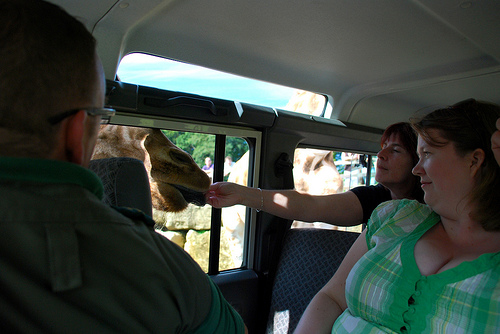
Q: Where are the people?
A: Inside a bus.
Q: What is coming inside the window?
A: A giraffe.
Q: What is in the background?
A: Another animal.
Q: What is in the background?
A: Other people and green trees.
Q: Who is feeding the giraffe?
A: A woman.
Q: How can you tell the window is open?
A: The giraffe is eating past it.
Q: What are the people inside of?
A: A bus.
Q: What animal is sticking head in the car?
A: Giraffe.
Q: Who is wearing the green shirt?
A: Woman closest to the camera.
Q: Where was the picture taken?
A: Inside car.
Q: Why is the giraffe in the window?
A: Get food.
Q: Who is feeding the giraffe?
A: Woman in back.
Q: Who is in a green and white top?
A: Woman on right.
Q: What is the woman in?
A: Car.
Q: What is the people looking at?
A: Animals.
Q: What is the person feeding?
A: Giraffe.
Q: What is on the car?
A: Some people.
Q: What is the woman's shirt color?
A: Green and white.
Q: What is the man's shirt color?
A: Green.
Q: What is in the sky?
A: Clouds.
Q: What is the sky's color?
A: Blue.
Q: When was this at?
A: During the day time.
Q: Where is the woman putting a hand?
A: Through the window to the car.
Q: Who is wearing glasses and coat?
A: A man.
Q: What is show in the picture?
A: The side window of the car.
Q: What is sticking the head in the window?
A: The giraffe.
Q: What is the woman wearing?
A: A green and white shirt.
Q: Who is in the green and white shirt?
A: A woman.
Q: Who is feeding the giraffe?
A: The woman.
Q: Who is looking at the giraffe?
A: The man.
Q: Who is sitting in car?
A: A woman.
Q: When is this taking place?
A: Daytime.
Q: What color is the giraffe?
A: Brown and tan,.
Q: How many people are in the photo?
A: Three.